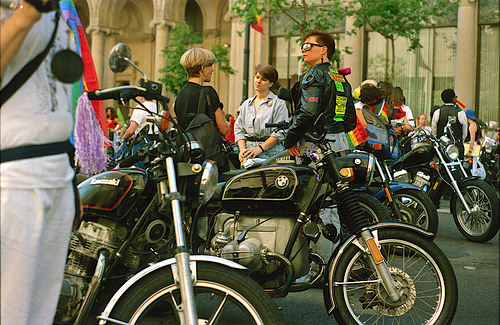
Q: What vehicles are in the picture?
A: Motorcycles.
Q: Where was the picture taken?
A: On a street.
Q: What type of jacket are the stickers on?
A: Leather.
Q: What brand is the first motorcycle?
A: Kawasaki.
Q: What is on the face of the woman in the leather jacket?
A: Sunglasses.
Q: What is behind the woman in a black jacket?
A: A motorcycle.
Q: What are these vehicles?
A: A group of motorcycles.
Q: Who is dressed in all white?
A: A woman.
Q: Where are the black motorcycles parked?
A: On the road.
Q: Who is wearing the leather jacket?
A: A woman.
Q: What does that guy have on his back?
A: Backpack.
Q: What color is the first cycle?
A: Black.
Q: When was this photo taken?
A: Daytime.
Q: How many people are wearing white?
A: 3.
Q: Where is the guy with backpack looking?
A: At the ladies.